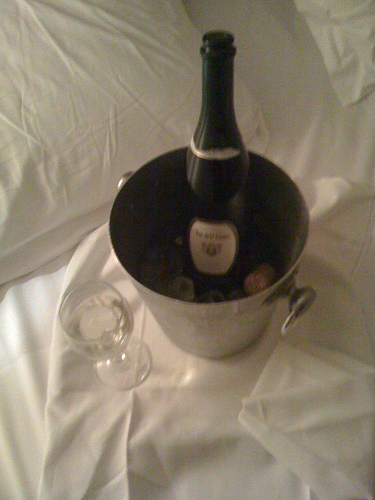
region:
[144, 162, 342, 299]
this is a bottle of wine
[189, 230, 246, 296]
the wine bottle is green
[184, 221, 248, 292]
this is the logo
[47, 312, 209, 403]
this is a glass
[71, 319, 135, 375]
the glass has water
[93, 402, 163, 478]
this is a wrinkle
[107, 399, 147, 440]
this is a crease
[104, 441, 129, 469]
this is pure white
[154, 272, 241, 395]
this is a bucket that is metal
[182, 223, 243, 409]
the bucket is silver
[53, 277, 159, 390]
A glass of wine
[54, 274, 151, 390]
A wineglass with wine in it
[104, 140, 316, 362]
A bucket of ice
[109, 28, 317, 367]
A glass bottle in a bucket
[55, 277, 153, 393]
A wine glass on a white sheet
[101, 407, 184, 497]
Crease in a sheet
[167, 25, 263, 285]
A dark green glass bottle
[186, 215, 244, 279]
A white label on a bottle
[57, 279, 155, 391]
A glass of champagne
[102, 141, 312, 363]
A silver bucket of ice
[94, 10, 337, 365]
A bottle of wine in an ice bucket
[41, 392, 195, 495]
A white bed sheet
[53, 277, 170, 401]
A wine glass filled with wine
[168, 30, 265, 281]
A bottle of champagne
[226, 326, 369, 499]
White cloth napkins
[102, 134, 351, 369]
A silver metal ice bucket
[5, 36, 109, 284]
A white bed pillow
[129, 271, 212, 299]
Ice cubes in a metal bucket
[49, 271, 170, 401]
A glass of champagne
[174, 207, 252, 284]
A label on a wine bottle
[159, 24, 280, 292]
A champagne bottle in a bucket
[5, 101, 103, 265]
A bed pillow with a wrinkly cover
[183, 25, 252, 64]
The mouth of a wine bottle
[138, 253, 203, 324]
Ice cubes in a bucket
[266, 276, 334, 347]
The silver metal handle of an ice bucket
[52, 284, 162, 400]
A wine glass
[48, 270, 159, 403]
The glass has champagne in it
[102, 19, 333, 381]
The champagne is in a bucket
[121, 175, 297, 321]
The bucket is full of ice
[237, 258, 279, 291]
The champagne cork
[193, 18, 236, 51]
The champagne is open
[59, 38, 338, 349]
The champagne is on a bed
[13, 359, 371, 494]
Bed is covered in white sheets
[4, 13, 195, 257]
Pillow at the head of the bed